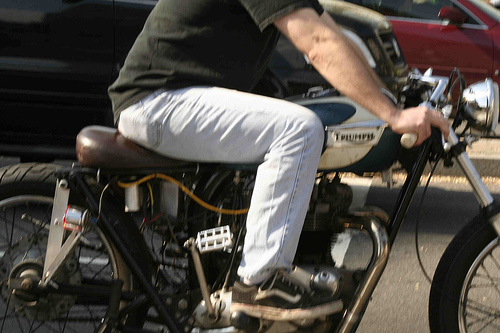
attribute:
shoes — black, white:
[229, 272, 349, 319]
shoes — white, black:
[229, 265, 348, 321]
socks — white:
[237, 267, 275, 288]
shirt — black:
[108, 0, 325, 118]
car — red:
[341, 2, 499, 107]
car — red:
[341, 0, 497, 95]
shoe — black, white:
[229, 270, 347, 325]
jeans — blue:
[116, 83, 326, 285]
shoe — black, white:
[226, 274, 344, 324]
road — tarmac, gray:
[312, 133, 499, 331]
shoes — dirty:
[223, 277, 358, 326]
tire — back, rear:
[1, 153, 140, 331]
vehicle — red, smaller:
[378, 0, 499, 76]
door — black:
[115, 1, 170, 77]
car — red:
[379, 3, 492, 88]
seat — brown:
[74, 115, 123, 165]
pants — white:
[109, 83, 337, 267]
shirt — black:
[113, 2, 285, 98]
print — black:
[329, 126, 381, 147]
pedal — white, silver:
[191, 219, 236, 255]